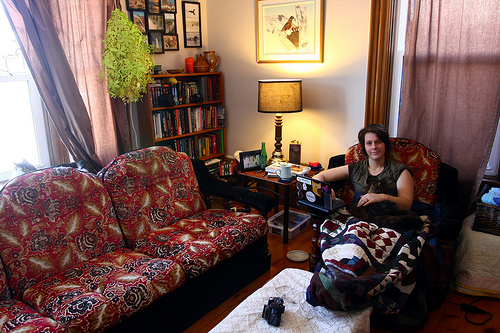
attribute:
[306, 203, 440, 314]
blanket — multi colored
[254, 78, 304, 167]
standing lamp — illimunated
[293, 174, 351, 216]
laptop — small, turned on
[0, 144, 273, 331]
sofa — red, floral, black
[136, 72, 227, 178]
bookshelf — fully stacked, covered with books, wooden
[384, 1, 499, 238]
window curtain shade — mauve, open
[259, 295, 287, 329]
camera — black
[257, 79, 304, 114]
shade — brown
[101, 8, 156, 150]
tree — hanging, green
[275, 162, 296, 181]
cup — white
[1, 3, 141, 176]
curtain — brown, drawn, open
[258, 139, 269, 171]
bottle — green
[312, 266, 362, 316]
feet — propped up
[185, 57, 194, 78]
candle — red